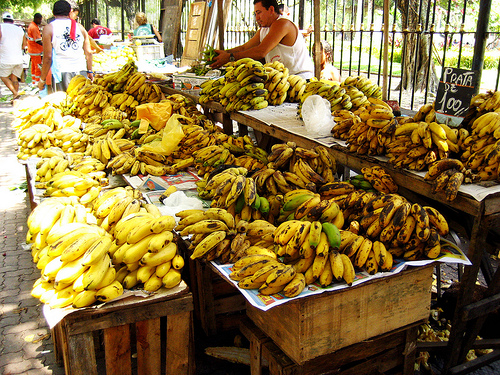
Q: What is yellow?
A: Bananas.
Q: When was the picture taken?
A: Daytime.